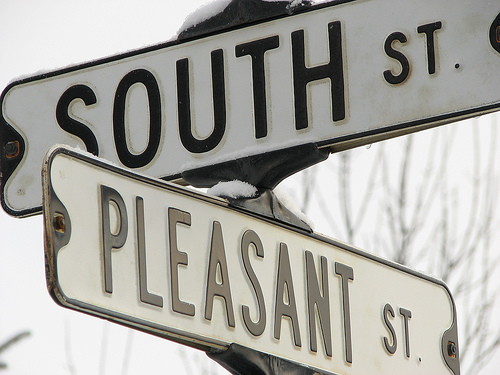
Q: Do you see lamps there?
A: No, there are no lamps.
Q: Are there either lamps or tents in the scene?
A: No, there are no lamps or tents.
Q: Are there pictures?
A: No, there are no pictures.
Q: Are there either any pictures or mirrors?
A: No, there are no pictures or mirrors.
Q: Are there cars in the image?
A: No, there are no cars.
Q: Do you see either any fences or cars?
A: No, there are no cars or fences.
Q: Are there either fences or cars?
A: No, there are no cars or fences.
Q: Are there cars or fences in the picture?
A: No, there are no cars or fences.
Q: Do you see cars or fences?
A: No, there are no cars or fences.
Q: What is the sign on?
A: The sign is on the pole.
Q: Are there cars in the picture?
A: No, there are no cars.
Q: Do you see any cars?
A: No, there are no cars.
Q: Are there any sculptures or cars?
A: No, there are no cars or sculptures.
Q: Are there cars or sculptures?
A: No, there are no cars or sculptures.